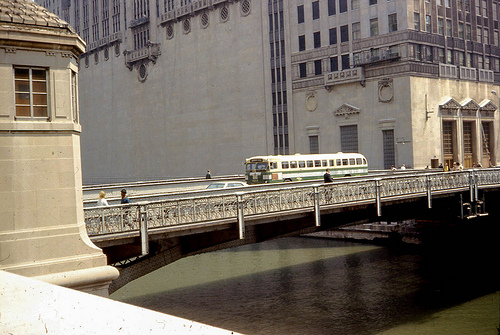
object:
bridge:
[81, 168, 500, 296]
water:
[103, 236, 500, 335]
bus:
[242, 151, 369, 185]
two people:
[97, 188, 135, 234]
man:
[323, 168, 334, 183]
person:
[206, 170, 211, 179]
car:
[206, 181, 248, 189]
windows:
[281, 157, 366, 169]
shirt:
[443, 165, 450, 171]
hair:
[99, 191, 106, 198]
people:
[391, 162, 483, 171]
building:
[0, 0, 120, 298]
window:
[297, 5, 305, 24]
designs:
[199, 13, 209, 29]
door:
[442, 120, 452, 171]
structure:
[189, 24, 411, 143]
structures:
[10, 6, 83, 58]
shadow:
[116, 230, 499, 334]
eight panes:
[12, 64, 50, 121]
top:
[211, 181, 244, 184]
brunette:
[453, 160, 463, 172]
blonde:
[97, 191, 110, 234]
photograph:
[0, 0, 499, 335]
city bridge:
[84, 167, 500, 257]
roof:
[0, 0, 87, 56]